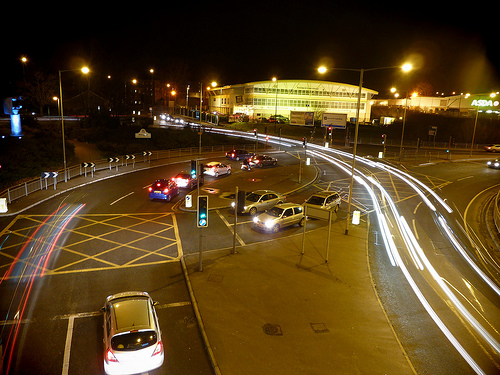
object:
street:
[362, 153, 499, 374]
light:
[148, 187, 168, 193]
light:
[81, 65, 90, 74]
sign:
[81, 162, 96, 168]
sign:
[107, 157, 119, 163]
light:
[156, 183, 161, 187]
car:
[149, 179, 180, 202]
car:
[301, 191, 341, 220]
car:
[253, 202, 305, 233]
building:
[202, 78, 379, 124]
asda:
[370, 86, 500, 114]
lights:
[317, 63, 412, 74]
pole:
[330, 66, 410, 235]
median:
[180, 213, 417, 374]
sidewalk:
[0, 150, 226, 216]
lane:
[0, 199, 223, 374]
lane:
[365, 163, 497, 372]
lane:
[157, 113, 499, 374]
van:
[302, 191, 342, 221]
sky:
[2, 3, 498, 151]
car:
[100, 291, 166, 374]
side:
[144, 292, 164, 361]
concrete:
[183, 213, 412, 375]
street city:
[2, 57, 497, 375]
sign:
[302, 203, 338, 223]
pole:
[301, 205, 306, 253]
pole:
[325, 211, 332, 262]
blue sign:
[9, 105, 24, 140]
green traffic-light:
[199, 213, 208, 226]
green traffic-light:
[190, 169, 196, 178]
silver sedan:
[231, 190, 287, 216]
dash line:
[412, 175, 475, 240]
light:
[265, 220, 274, 228]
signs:
[41, 151, 153, 178]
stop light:
[196, 195, 209, 228]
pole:
[199, 228, 204, 271]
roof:
[203, 80, 379, 99]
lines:
[2, 150, 500, 374]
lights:
[206, 76, 277, 90]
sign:
[41, 171, 59, 179]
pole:
[40, 177, 57, 190]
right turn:
[174, 172, 413, 257]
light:
[317, 66, 327, 73]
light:
[401, 62, 412, 73]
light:
[272, 77, 277, 82]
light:
[210, 81, 217, 88]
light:
[206, 86, 211, 90]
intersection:
[150, 112, 500, 170]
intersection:
[0, 141, 499, 375]